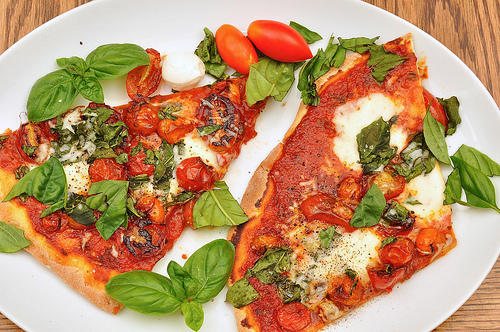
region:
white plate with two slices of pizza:
[2, 2, 499, 328]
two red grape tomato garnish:
[216, 18, 316, 68]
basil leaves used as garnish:
[108, 238, 233, 330]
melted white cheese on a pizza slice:
[403, 164, 445, 216]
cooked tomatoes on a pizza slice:
[96, 103, 214, 188]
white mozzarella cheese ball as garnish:
[159, 51, 209, 88]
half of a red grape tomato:
[126, 48, 162, 95]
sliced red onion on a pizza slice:
[196, 93, 238, 141]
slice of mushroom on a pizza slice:
[19, 120, 42, 156]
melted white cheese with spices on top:
[281, 220, 378, 304]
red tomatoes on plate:
[218, 22, 322, 93]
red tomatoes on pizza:
[40, 93, 225, 242]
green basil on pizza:
[277, 70, 440, 293]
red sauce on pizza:
[242, 124, 364, 293]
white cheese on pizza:
[332, 81, 426, 220]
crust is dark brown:
[202, 124, 306, 320]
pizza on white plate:
[44, 50, 499, 315]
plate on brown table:
[1, 0, 476, 317]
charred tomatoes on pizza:
[59, 82, 272, 273]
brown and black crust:
[205, 172, 280, 290]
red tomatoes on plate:
[195, 13, 292, 79]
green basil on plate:
[10, 42, 173, 122]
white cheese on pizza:
[27, 98, 214, 227]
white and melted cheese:
[224, 219, 384, 324]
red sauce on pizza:
[272, 174, 365, 307]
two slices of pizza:
[48, 34, 375, 309]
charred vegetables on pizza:
[65, 79, 375, 282]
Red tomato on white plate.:
[251, 24, 308, 76]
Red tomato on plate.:
[218, 18, 261, 85]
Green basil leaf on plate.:
[465, 163, 491, 214]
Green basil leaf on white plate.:
[146, 257, 184, 325]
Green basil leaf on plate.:
[66, 58, 113, 100]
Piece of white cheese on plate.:
[168, 48, 206, 92]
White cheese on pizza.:
[51, 142, 91, 185]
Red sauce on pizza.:
[72, 223, 130, 269]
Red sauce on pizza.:
[292, 151, 314, 182]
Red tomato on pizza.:
[278, 296, 310, 330]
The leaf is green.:
[83, 39, 155, 85]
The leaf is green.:
[23, 67, 80, 127]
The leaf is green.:
[97, 255, 189, 318]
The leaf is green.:
[167, 255, 198, 305]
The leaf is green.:
[178, 293, 206, 330]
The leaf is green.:
[181, 232, 239, 307]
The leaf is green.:
[72, 70, 108, 109]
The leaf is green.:
[418, 88, 455, 175]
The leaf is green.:
[1, 208, 35, 261]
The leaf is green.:
[2, 143, 76, 218]